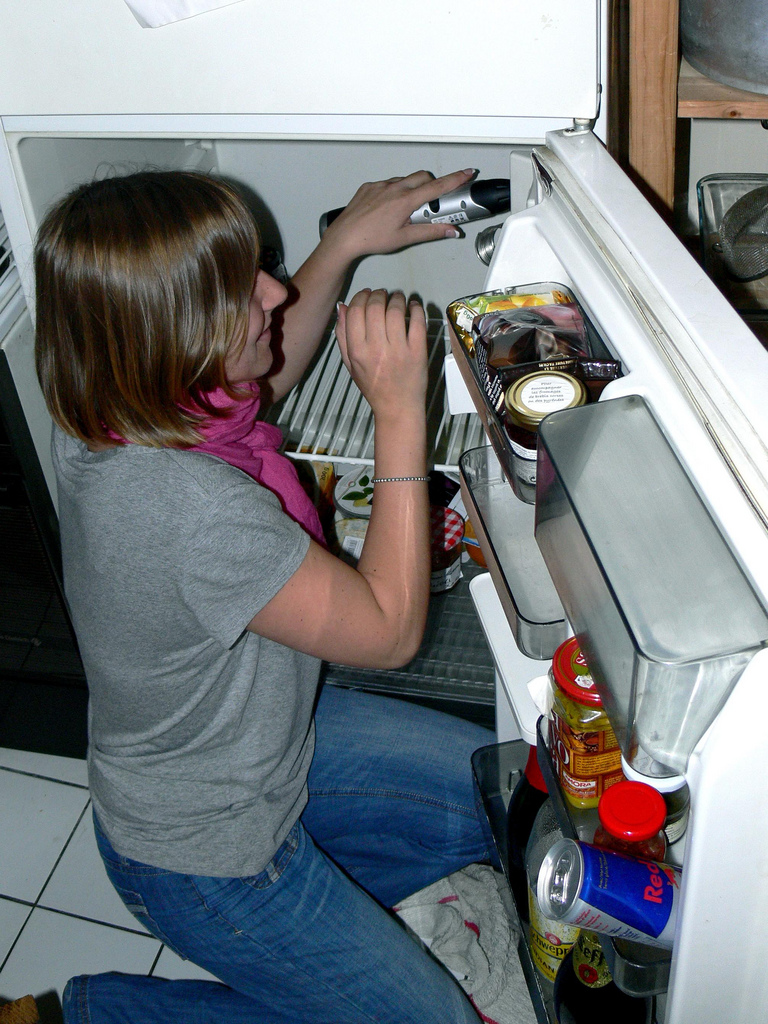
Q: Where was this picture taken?
A: In a house.